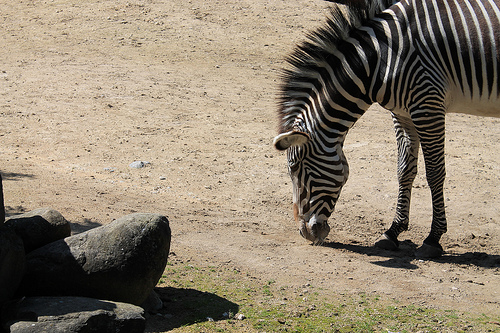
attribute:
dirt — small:
[154, 198, 360, 306]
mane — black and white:
[256, 0, 380, 132]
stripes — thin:
[378, 72, 413, 95]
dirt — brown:
[4, 3, 281, 233]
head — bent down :
[275, 117, 347, 241]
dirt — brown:
[32, 135, 59, 167]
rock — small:
[127, 160, 148, 170]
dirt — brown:
[15, 9, 270, 216]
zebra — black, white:
[252, 7, 410, 259]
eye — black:
[288, 160, 301, 173]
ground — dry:
[139, 83, 238, 161]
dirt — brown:
[70, 64, 224, 159]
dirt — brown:
[94, 80, 150, 85]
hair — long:
[260, 37, 359, 88]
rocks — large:
[2, 187, 187, 329]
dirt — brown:
[109, 31, 232, 132]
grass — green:
[245, 285, 325, 331]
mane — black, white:
[247, 9, 321, 114]